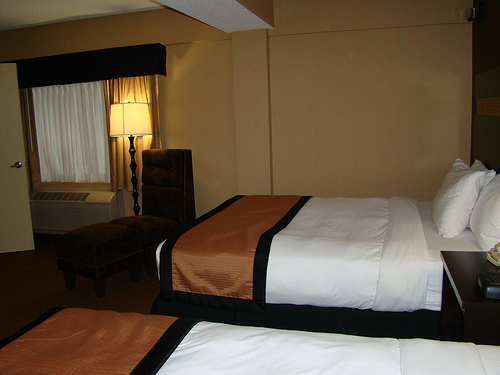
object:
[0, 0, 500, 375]
bedroom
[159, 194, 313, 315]
stripe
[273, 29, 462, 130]
wall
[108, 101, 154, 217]
lamp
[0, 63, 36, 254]
open door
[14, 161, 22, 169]
handle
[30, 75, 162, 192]
closed curtains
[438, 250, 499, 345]
nightstand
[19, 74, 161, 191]
window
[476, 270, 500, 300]
alarm clock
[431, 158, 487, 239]
pillow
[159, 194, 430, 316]
bed cover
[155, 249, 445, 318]
bedskirt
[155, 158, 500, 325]
bed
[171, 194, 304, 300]
orange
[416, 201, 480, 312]
bed sheet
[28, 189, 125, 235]
radiator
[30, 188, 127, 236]
unit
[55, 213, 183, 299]
chair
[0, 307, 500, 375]
bed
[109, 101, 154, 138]
lampshade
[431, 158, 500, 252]
pillows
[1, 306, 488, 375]
bed cover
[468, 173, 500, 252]
pillow